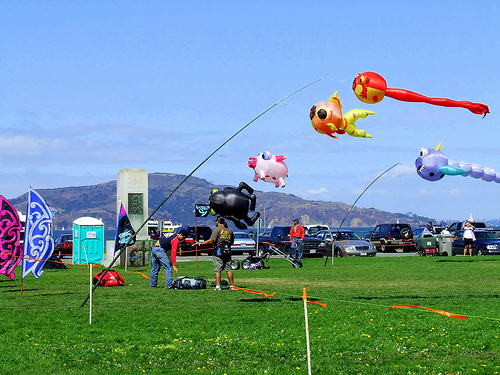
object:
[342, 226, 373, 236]
water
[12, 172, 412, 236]
hill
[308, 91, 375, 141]
kite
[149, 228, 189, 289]
man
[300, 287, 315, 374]
post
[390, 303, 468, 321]
streamers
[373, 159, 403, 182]
banner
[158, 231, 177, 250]
jacket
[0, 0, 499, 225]
sky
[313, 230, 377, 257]
car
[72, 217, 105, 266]
port a potty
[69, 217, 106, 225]
roof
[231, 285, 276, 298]
flag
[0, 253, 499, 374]
field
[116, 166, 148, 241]
structure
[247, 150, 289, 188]
kite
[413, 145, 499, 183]
balloon